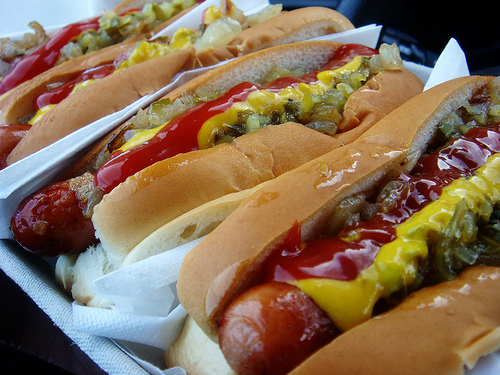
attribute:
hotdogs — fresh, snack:
[33, 34, 462, 362]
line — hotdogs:
[31, 76, 273, 323]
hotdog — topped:
[9, 150, 177, 256]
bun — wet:
[120, 170, 208, 240]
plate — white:
[4, 268, 116, 371]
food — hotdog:
[303, 37, 466, 286]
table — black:
[5, 298, 40, 348]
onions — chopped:
[138, 99, 192, 122]